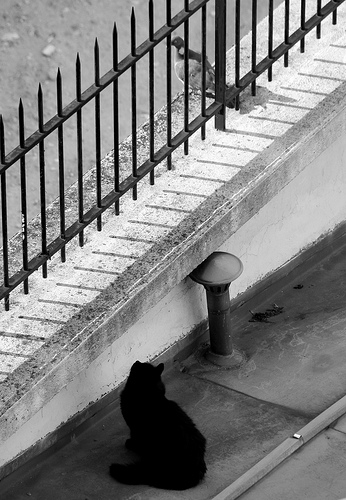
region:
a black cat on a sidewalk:
[113, 331, 212, 499]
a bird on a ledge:
[145, 24, 240, 136]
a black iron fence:
[16, 26, 210, 228]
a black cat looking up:
[109, 324, 191, 447]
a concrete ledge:
[34, 82, 330, 302]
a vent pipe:
[192, 237, 251, 392]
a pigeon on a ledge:
[126, 7, 238, 168]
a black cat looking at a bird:
[101, 16, 236, 494]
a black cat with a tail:
[91, 342, 207, 497]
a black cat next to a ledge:
[64, 328, 236, 499]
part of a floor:
[223, 412, 255, 449]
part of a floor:
[212, 413, 245, 441]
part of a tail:
[103, 460, 138, 483]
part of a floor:
[213, 332, 283, 431]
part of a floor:
[202, 405, 259, 440]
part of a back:
[143, 402, 189, 446]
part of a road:
[304, 448, 345, 478]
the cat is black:
[112, 366, 220, 497]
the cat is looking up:
[110, 359, 216, 490]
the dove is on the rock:
[163, 35, 230, 97]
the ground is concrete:
[226, 379, 282, 440]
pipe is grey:
[203, 293, 243, 344]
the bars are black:
[102, 24, 192, 187]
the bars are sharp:
[107, 14, 185, 189]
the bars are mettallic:
[90, 34, 151, 204]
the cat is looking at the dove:
[108, 354, 240, 493]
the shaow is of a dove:
[250, 87, 275, 114]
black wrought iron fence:
[52, 46, 322, 193]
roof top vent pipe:
[172, 249, 256, 377]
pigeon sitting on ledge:
[157, 23, 259, 116]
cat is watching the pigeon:
[120, 18, 219, 458]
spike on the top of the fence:
[37, 52, 108, 134]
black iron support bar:
[200, 6, 241, 148]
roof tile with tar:
[173, 258, 325, 389]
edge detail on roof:
[201, 397, 333, 497]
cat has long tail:
[100, 449, 219, 493]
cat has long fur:
[98, 348, 209, 498]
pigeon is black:
[166, 33, 241, 115]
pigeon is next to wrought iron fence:
[164, 32, 243, 113]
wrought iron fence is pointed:
[52, 46, 88, 118]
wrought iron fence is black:
[29, 53, 170, 281]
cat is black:
[108, 353, 208, 491]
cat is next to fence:
[102, 356, 216, 490]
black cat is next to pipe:
[106, 356, 211, 493]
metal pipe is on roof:
[191, 250, 243, 367]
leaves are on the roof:
[240, 298, 286, 329]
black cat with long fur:
[103, 351, 209, 490]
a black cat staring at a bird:
[53, 361, 246, 494]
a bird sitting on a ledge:
[137, 26, 246, 117]